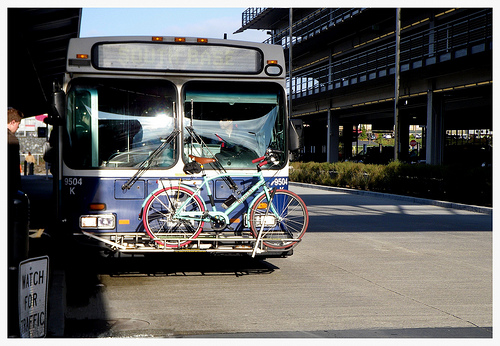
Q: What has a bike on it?
A: The carrier.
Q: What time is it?
A: Afternoon.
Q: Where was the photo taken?
A: Outside somewhere.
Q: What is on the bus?
A: Black wipers.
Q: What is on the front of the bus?
A: Bike rack.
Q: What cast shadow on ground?
A: Building.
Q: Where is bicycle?
A: Front of bus.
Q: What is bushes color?
A: Green.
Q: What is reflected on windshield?
A: Light.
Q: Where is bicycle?
A: Front of bus.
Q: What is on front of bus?
A: Window.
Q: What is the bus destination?
A: South base.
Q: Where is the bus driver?
A: On the bus.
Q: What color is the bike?
A: Aqua blue.